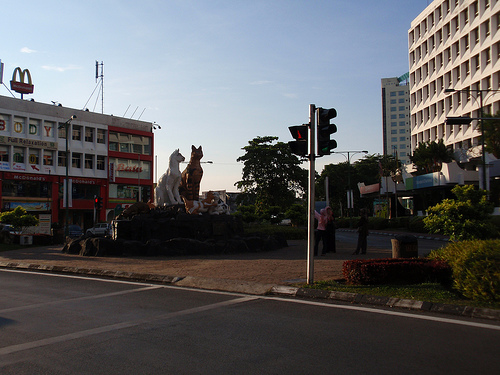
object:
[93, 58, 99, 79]
sign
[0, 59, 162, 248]
building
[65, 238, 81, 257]
rocks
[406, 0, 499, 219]
tall building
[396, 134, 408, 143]
windows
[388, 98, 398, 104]
windows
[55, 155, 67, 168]
windows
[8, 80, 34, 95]
sign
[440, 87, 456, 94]
street lights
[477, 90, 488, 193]
post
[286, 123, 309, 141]
light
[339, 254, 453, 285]
bushes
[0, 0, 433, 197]
sky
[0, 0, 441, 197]
clouds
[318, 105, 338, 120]
light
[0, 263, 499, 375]
street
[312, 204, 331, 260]
person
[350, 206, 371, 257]
person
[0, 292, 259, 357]
white lines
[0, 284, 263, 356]
cross walk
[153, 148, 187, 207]
statues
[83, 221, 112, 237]
vehicles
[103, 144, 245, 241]
center